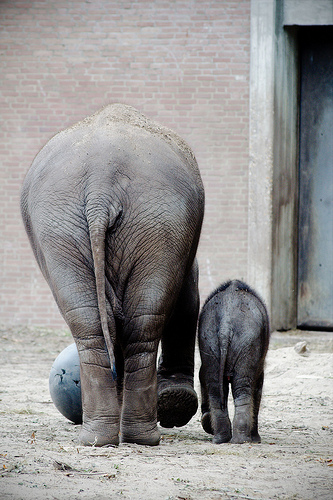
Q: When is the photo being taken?
A: Daytime.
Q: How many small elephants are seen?
A: One.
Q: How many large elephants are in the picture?
A: One.